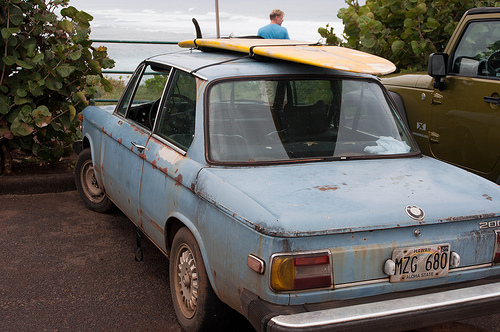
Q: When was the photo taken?
A: Daytime.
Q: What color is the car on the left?
A: Blue.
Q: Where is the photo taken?
A: Beach.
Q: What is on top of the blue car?
A: Surfboard.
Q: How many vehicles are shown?
A: Two.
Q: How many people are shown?
A: One.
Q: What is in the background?
A: Water.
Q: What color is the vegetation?
A: Green.